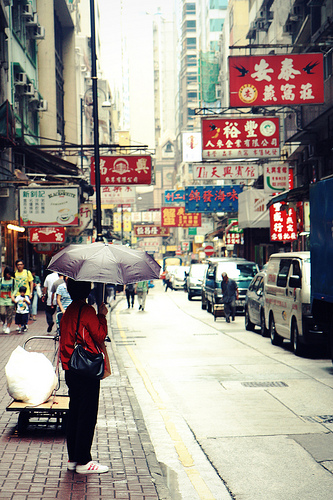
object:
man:
[220, 268, 238, 331]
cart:
[207, 289, 233, 320]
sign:
[199, 113, 279, 161]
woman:
[49, 276, 119, 473]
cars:
[156, 248, 332, 359]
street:
[125, 256, 331, 498]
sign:
[223, 51, 325, 109]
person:
[12, 255, 36, 328]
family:
[1, 257, 34, 335]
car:
[246, 268, 269, 329]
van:
[201, 255, 251, 321]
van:
[264, 253, 316, 351]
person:
[43, 278, 125, 477]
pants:
[64, 368, 99, 461]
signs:
[157, 208, 228, 239]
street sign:
[203, 245, 214, 256]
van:
[262, 249, 326, 357]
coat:
[57, 316, 110, 364]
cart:
[4, 332, 74, 446]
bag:
[65, 332, 110, 386]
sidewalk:
[0, 287, 169, 499]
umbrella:
[42, 235, 163, 336]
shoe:
[66, 461, 76, 470]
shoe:
[76, 461, 109, 474]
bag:
[4, 344, 60, 407]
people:
[122, 274, 151, 314]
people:
[2, 261, 60, 333]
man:
[8, 252, 37, 323]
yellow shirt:
[11, 268, 35, 298]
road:
[75, 230, 325, 414]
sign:
[193, 165, 258, 179]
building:
[152, 0, 329, 292]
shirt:
[12, 266, 35, 305]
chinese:
[201, 118, 274, 156]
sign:
[184, 183, 254, 212]